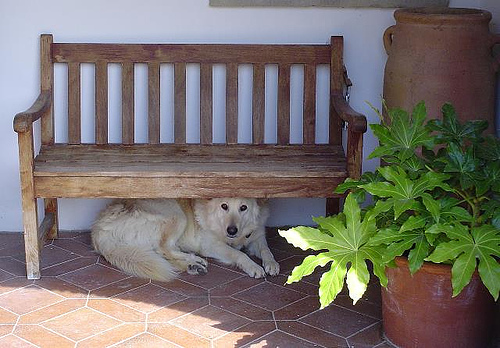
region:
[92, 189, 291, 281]
A white fluffy dog peeking out from under a bench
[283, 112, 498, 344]
A potted plant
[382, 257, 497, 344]
A red plant pot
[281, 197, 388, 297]
The big green leaf of a plant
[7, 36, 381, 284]
A wooden bench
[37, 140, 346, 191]
The seat of a bench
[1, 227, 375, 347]
A red tile floor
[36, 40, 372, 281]
A dog hiding under a bench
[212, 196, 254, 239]
A dog's face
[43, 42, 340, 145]
The back of a bench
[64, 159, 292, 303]
dog is under the bench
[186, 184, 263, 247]
dog is looking at the camera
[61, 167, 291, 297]
the dog is beige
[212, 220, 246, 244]
the nose is black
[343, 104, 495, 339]
a potted green plant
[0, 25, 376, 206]
the bench is light brown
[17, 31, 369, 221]
the bench is made of wood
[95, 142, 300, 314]
the dog is in the shade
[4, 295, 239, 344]
sun is on the ground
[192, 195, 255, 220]
the eyes are open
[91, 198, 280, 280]
a tan dog laying down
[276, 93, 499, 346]
a full potted plant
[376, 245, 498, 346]
a large clay pot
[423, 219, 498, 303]
a bright green leaf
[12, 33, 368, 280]
an empty wooden bench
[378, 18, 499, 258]
a tall clay pot with a handle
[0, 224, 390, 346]
white and brown tile floor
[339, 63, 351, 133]
a metal chain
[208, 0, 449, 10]
bottom of a wooden window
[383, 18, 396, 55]
handle on a clay pot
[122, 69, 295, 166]
A wooden bench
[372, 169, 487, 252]
Potted plant in the photo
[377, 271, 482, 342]
A pot for the plant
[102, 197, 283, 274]
A dog under the bench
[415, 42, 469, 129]
A small tank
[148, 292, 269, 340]
Tiles on the floor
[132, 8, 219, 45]
A wall in the photo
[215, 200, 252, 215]
eyes of a dog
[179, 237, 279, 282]
Legs of a dog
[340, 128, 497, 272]
leaves on a potted plant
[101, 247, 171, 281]
the dog's tail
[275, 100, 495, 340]
a ceramic plant pot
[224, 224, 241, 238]
the nose of a dog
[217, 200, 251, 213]
the eyes of a dog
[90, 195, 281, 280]
the dog is under a bench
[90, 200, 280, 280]
the dog is white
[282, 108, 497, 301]
the artificial plant leaves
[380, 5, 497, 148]
a big ceramic pot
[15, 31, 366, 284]
the bench has a dog under it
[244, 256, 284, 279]
the paws of a dog